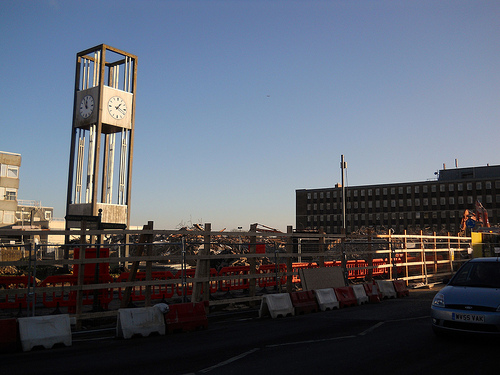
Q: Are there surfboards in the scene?
A: No, there are no surfboards.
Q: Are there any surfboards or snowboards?
A: No, there are no surfboards or snowboards.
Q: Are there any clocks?
A: Yes, there is a clock.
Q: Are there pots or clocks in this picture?
A: Yes, there is a clock.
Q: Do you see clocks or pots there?
A: Yes, there is a clock.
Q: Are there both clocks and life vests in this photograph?
A: No, there is a clock but no life jackets.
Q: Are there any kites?
A: No, there are no kites.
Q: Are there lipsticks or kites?
A: No, there are no kites or lipsticks.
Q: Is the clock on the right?
A: No, the clock is on the left of the image.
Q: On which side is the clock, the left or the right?
A: The clock is on the left of the image.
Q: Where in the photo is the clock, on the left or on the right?
A: The clock is on the left of the image.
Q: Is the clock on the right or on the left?
A: The clock is on the left of the image.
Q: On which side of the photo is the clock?
A: The clock is on the left of the image.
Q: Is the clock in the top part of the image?
A: Yes, the clock is in the top of the image.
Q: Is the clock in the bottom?
A: No, the clock is in the top of the image.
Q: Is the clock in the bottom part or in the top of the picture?
A: The clock is in the top of the image.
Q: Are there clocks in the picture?
A: Yes, there is a clock.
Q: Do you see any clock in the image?
A: Yes, there is a clock.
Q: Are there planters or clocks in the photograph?
A: Yes, there is a clock.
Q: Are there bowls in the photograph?
A: No, there are no bowls.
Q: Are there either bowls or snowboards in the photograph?
A: No, there are no bowls or snowboards.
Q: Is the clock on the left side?
A: Yes, the clock is on the left of the image.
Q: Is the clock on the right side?
A: No, the clock is on the left of the image.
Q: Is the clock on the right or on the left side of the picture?
A: The clock is on the left of the image.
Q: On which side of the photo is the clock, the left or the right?
A: The clock is on the left of the image.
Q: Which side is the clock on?
A: The clock is on the left of the image.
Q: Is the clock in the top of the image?
A: Yes, the clock is in the top of the image.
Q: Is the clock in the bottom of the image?
A: No, the clock is in the top of the image.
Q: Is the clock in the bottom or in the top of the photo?
A: The clock is in the top of the image.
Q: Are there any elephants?
A: Yes, there is an elephant.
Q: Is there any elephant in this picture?
A: Yes, there is an elephant.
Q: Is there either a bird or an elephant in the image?
A: Yes, there is an elephant.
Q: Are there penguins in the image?
A: No, there are no penguins.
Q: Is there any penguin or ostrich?
A: No, there are no penguins or ostriches.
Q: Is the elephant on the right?
A: Yes, the elephant is on the right of the image.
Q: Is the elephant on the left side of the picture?
A: No, the elephant is on the right of the image.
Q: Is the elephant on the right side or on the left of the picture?
A: The elephant is on the right of the image.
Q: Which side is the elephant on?
A: The elephant is on the right of the image.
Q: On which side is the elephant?
A: The elephant is on the right of the image.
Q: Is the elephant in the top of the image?
A: Yes, the elephant is in the top of the image.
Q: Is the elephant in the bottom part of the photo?
A: No, the elephant is in the top of the image.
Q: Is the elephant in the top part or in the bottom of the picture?
A: The elephant is in the top of the image.